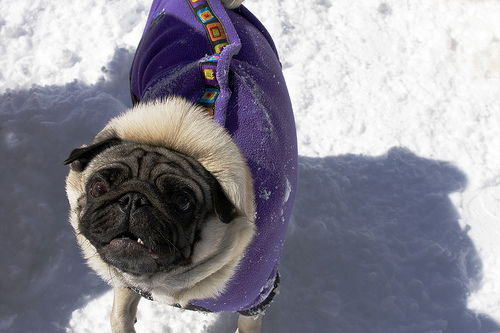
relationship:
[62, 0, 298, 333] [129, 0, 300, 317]
pug dog wearing vest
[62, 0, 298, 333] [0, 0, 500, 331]
pug dog standing in snow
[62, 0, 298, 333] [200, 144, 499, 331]
pug dog has shadow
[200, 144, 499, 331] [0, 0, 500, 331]
shadow on top of snow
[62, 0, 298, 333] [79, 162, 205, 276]
pug dog has face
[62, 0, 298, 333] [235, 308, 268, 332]
pug dog has front leg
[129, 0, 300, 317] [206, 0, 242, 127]
vest has closure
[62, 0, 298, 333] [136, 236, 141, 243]
pug dog has tooth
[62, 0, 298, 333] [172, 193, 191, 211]
pug dog has eye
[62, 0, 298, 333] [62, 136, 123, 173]
pug dog has right ear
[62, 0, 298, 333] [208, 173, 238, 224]
pug dog has left ear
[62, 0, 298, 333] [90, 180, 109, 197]
pug dog has right eye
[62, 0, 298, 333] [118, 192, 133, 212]
pug dog has right nostril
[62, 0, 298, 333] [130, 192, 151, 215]
pug dog has left nostril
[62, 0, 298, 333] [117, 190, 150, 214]
pug dog has nose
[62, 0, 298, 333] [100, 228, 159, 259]
pug dog has mouth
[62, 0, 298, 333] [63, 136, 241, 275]
pug dog has head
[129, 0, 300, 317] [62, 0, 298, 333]
vest worn on pug dog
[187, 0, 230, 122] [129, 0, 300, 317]
stripe on top of vest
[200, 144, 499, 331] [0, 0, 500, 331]
shadow in top of snow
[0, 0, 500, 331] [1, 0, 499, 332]
snow laying on ground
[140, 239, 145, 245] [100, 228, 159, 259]
tooth inside of mouth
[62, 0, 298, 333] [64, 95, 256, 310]
pug dog has fur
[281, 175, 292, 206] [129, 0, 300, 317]
snow on top of vest